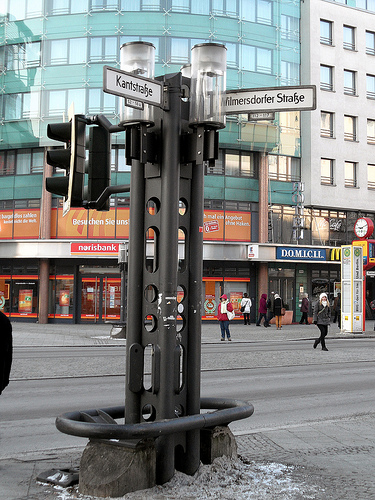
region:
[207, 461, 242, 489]
snow on the sidewalk.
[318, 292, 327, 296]
hat on woman's head.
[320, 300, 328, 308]
scarf around woman's neck.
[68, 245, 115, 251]
red sign on building.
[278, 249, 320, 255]
blue sign on building.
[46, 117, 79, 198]
traffic light on pole.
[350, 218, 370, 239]
clock near the building.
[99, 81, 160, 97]
street sign on pole.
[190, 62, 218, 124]
light on the pole.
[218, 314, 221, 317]
red coat on woman.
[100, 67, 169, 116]
A direction sign post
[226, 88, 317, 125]
A direction sign post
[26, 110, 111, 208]
A trafic light signal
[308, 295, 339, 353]
A person walking in the street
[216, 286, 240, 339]
A person walking in the street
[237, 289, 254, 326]
A person walking in the street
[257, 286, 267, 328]
A person walking in the street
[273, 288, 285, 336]
A person walking in the street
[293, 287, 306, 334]
A person walking in the street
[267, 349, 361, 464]
A grey tarmac road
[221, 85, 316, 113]
White and gray sign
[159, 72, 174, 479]
Post made from metal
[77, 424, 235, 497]
Base made of cement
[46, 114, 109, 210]
A black traffic light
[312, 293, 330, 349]
Someone is walking on the road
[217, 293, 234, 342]
A woman is walking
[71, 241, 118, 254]
Sign on the building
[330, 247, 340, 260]
McDonalds logo on building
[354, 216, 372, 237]
A red and white clock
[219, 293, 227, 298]
The hat is red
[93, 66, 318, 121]
street signs in a foreign language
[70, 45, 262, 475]
metal contraption with street signs on it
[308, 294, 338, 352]
woman walking across the street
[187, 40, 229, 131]
cylindrical light next to the street sign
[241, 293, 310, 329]
people walking on the sidewalk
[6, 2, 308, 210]
building made of windows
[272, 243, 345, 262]
sign over a business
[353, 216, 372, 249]
tall red clock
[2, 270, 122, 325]
red bordered windows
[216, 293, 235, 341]
woman wearing a red hoodie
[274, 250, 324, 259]
blue sign on building.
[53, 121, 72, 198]
traffic light on the pole.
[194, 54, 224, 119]
street light on pole.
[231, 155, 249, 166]
windows on the building.